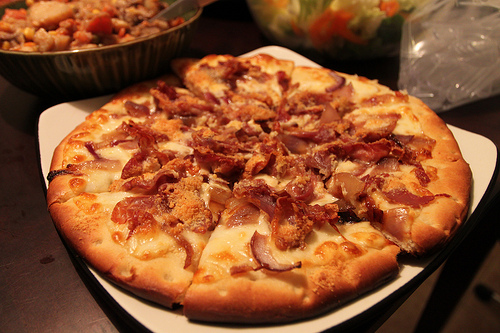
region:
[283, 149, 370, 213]
top of a pizza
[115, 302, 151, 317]
part of a plate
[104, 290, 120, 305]
edge of a plate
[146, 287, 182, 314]
edge of a pizza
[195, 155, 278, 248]
top of a pizza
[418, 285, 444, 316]
part of a floor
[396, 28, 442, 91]
part of a polythene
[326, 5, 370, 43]
part of a salad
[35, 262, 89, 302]
surface of a table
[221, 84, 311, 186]
part of a pizza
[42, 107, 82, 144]
the plate is white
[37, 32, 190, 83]
the dish is metal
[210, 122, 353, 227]
bacon is on pizza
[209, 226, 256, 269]
the cheese is on pizza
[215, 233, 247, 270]
the cheese is melted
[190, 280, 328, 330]
the crust is brown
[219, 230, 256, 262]
the cheese is yellow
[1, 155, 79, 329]
the table is black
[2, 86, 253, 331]
plate is on table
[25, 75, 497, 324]
pizza is on the plate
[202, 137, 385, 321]
a sliced piece of pizza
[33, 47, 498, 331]
a solid white plate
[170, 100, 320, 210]
concentrated area of meat pizza toppings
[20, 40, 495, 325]
a whole pizza on the plate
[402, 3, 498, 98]
bag of clear plastic utensils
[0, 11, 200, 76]
a circular tin dish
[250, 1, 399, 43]
bowl of salad greens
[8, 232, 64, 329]
top of brown table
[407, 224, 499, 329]
the table leg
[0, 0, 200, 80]
food in a metal container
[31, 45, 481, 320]
Thick crust pizza.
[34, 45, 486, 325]
Something for a hungry person.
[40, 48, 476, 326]
A homemade pizza is ready.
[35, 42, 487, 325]
Possibly a meat lovers pie.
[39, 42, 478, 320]
Really good food.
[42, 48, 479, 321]
Looks like bacon on top.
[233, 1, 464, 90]
Appears to be a meal with salad.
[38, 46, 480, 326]
Already sliced and waiting.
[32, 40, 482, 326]
No one has eaten yet.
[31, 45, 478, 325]
Covers the plate.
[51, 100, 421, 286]
this is a pizza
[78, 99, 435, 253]
the pizza is big in size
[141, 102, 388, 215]
the pizza is spicy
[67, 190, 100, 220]
the pizza is brown in color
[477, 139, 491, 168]
this is a plate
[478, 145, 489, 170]
the plate is white in color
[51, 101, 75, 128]
the plate is curvy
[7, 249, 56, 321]
this is a table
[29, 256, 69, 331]
the table is grey in color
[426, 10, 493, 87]
this is a polythene paper